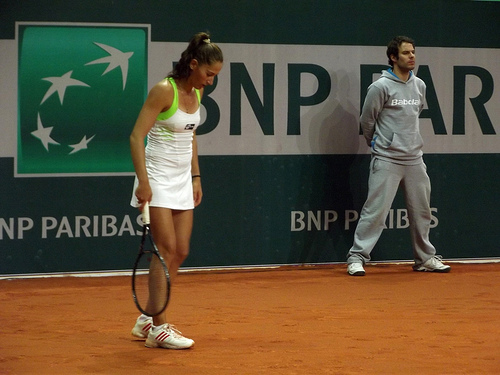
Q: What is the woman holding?
A: A tennis racket.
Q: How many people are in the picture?
A: Two.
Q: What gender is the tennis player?
A: Female.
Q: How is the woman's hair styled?
A: Ponytail.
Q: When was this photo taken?
A: During a tennis match.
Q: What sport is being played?
A: Tennis.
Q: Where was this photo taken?
A: At a tennis court.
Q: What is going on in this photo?
A: A tennis match.